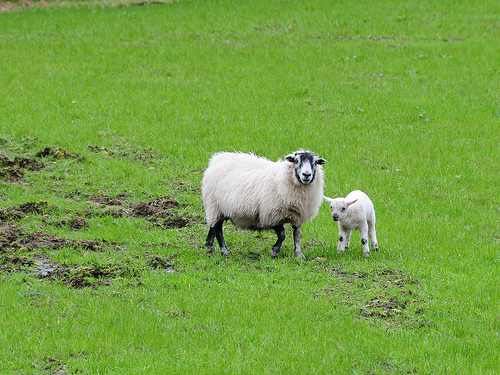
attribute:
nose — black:
[333, 212, 338, 225]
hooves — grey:
[264, 236, 292, 258]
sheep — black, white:
[196, 149, 339, 259]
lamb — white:
[317, 188, 375, 255]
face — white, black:
[294, 153, 316, 183]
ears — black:
[286, 155, 326, 162]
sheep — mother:
[198, 137, 328, 268]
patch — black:
[361, 237, 368, 246]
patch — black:
[336, 233, 346, 243]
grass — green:
[135, 280, 313, 363]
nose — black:
[301, 170, 311, 177]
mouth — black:
[302, 177, 312, 184]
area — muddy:
[5, 195, 178, 271]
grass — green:
[3, 0, 498, 144]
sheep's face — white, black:
[285, 148, 325, 184]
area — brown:
[1, 0, 171, 12]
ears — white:
[321, 190, 358, 205]